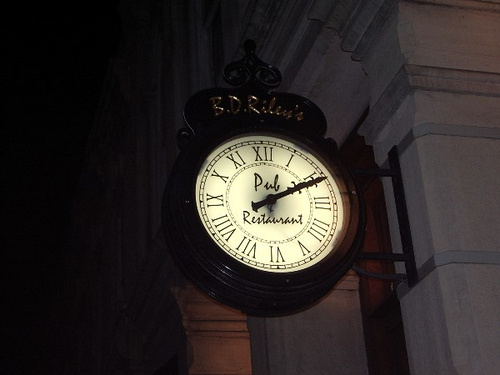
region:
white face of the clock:
[214, 150, 335, 256]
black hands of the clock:
[250, 173, 325, 216]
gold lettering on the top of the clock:
[196, 85, 315, 140]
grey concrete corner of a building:
[386, 17, 492, 357]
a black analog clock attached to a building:
[141, 53, 441, 318]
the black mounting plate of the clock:
[363, 136, 438, 311]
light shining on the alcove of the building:
[168, 294, 258, 374]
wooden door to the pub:
[351, 138, 413, 374]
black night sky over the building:
[3, 6, 120, 268]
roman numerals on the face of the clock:
[214, 227, 336, 262]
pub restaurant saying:
[239, 170, 306, 229]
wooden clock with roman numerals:
[170, 129, 360, 310]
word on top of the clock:
[210, 85, 312, 128]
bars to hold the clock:
[352, 160, 429, 284]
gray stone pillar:
[390, 37, 494, 169]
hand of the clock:
[260, 168, 325, 193]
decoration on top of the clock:
[219, 34, 283, 88]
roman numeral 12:
[250, 141, 273, 163]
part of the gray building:
[15, 29, 162, 219]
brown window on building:
[354, 283, 416, 368]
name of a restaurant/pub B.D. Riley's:
[206, 91, 306, 122]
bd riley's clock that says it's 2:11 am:
[186, 130, 342, 275]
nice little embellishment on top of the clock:
[217, 34, 284, 88]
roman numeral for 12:
[250, 143, 275, 166]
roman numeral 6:
[266, 243, 286, 265]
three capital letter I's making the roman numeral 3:
[311, 194, 333, 214]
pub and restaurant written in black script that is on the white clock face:
[238, 169, 306, 228]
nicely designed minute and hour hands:
[248, 171, 327, 212]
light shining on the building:
[172, 282, 254, 372]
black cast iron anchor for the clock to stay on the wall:
[349, 142, 421, 287]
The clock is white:
[180, 136, 344, 280]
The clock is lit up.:
[198, 122, 354, 284]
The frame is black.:
[178, 55, 380, 325]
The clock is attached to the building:
[344, 141, 416, 372]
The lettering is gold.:
[185, 75, 325, 136]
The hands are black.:
[240, 171, 332, 218]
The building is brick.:
[362, 20, 482, 374]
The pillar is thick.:
[303, 2, 498, 367]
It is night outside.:
[5, 8, 175, 374]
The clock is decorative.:
[164, 31, 426, 315]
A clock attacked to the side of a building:
[155, 32, 370, 319]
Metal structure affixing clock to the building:
[345, 147, 421, 288]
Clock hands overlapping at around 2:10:
[251, 176, 328, 211]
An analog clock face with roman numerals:
[192, 134, 344, 276]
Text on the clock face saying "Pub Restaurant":
[242, 172, 304, 226]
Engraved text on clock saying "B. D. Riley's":
[208, 93, 304, 122]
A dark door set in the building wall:
[325, 100, 409, 373]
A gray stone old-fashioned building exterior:
[44, 0, 498, 373]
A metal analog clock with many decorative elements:
[162, 36, 369, 316]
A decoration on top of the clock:
[217, 43, 282, 89]